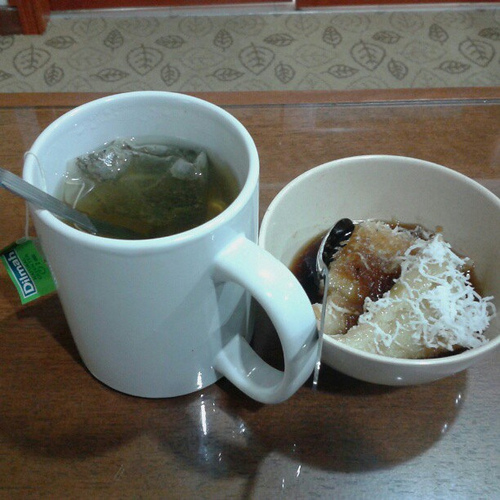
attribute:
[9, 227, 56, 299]
bag — green 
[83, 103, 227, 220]
tea — pouch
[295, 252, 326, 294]
coffee — black 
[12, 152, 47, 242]
thread — white 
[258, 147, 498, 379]
bowl — white 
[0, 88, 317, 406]
mug — white 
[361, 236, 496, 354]
coconut shreds — white 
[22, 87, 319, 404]
cup — white 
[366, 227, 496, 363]
coconut — white 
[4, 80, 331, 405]
cup — white 